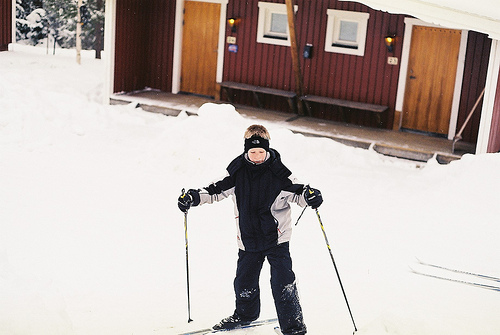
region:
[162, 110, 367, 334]
The little boy is wearing skis.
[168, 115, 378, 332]
The little boy is wearing a jacket.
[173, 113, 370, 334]
The little boy is wearing gloves.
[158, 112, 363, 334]
The little boy is wearing snowpants.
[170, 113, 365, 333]
The little boy is holding ski poles.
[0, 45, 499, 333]
The ground is snow covered.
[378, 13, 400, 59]
The light is on.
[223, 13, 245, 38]
The light is on.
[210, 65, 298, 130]
The bench is wood.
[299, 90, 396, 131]
The bench is wood.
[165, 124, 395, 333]
a young boy in a ski outfit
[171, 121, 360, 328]
a young boy holding 2 ski poles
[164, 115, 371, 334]
a young boy preparing to ski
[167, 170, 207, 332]
a ski pole in the upright position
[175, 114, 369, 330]
a young boy in a black ski suit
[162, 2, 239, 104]
a brown door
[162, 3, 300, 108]
a brown door and window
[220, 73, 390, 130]
2 benches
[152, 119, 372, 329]
a little boy attempting to ski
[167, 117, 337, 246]
a little boy wearing a black ski jacket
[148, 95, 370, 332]
A boy on ski's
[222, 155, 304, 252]
A black and grey jacket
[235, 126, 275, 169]
A black ski mask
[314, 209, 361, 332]
Black, silver and yellow ski pole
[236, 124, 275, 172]
A boy with blonde hair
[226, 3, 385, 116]
Red wood siding on building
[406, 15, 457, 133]
A light brown door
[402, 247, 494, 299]
Ski poles laying in the snow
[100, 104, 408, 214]
A bank of snow next to porch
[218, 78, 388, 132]
Two benches on porch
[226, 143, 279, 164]
boy is skying in front of his hotel room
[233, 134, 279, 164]
boy is learning another sport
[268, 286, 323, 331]
boy has fell in snow on right leg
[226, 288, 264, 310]
boy has fell on right leg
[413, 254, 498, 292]
someone is skiing along the side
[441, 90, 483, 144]
someone has shoveled the snow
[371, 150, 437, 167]
the stairs on the right are not shovelled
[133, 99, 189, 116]
the stairs on the left are not shovelled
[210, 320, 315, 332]
boy is watching his step in the snow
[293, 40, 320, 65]
the mailbox is empty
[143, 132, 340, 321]
A person skating on snow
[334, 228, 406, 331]
A white snow field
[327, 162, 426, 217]
A white snow field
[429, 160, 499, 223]
A white snow field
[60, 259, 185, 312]
A white snow field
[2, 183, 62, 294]
A white snow field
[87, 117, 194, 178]
A white snow field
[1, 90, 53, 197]
A white snow field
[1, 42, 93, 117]
A white snow field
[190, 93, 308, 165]
A white snow field